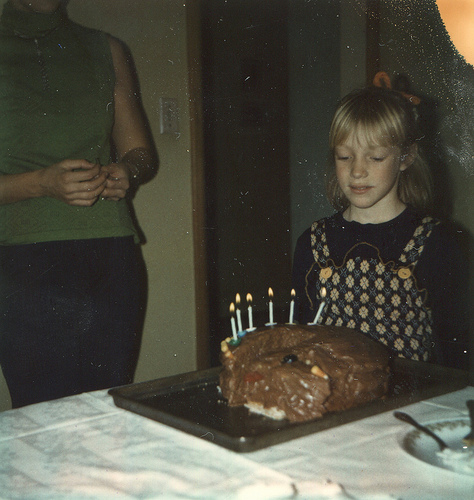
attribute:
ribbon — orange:
[374, 69, 418, 110]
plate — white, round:
[396, 413, 472, 488]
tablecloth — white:
[84, 453, 178, 499]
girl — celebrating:
[279, 82, 467, 367]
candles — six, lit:
[204, 280, 340, 343]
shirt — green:
[0, 16, 134, 227]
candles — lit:
[308, 280, 331, 325]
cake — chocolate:
[200, 328, 344, 390]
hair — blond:
[322, 82, 443, 214]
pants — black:
[0, 239, 145, 386]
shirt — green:
[0, 18, 150, 248]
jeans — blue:
[2, 232, 149, 410]